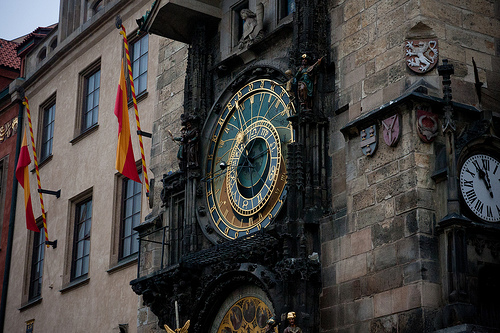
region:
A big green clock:
[162, 70, 315, 233]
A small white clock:
[442, 142, 499, 235]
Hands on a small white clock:
[475, 162, 495, 199]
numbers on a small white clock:
[459, 174, 483, 211]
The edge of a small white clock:
[449, 152, 468, 217]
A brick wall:
[331, 183, 412, 298]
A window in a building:
[28, 97, 59, 172]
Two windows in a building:
[23, 80, 107, 164]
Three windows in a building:
[16, 55, 157, 170]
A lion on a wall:
[383, 14, 447, 84]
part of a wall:
[359, 242, 389, 297]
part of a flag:
[115, 152, 142, 177]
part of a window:
[74, 247, 85, 261]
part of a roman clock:
[469, 189, 486, 218]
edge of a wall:
[407, 186, 428, 228]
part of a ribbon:
[118, 73, 144, 128]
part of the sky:
[19, 5, 44, 18]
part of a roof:
[3, 52, 13, 68]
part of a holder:
[45, 186, 60, 197]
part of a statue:
[243, 16, 259, 32]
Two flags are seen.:
[5, 35, 160, 218]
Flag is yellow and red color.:
[8, 82, 203, 235]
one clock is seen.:
[446, 130, 496, 210]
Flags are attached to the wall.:
[0, 90, 176, 240]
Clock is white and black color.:
[445, 150, 497, 216]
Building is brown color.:
[65, 158, 116, 178]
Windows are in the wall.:
[20, 87, 166, 282]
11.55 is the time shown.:
[441, 130, 497, 230]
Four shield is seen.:
[340, 20, 443, 156]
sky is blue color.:
[3, 5, 55, 27]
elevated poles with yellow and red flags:
[10, 12, 185, 248]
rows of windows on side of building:
[11, 25, 156, 310]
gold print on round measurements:
[180, 60, 302, 246]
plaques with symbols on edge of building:
[337, 85, 457, 160]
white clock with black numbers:
[436, 150, 492, 225]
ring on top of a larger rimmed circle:
[185, 65, 300, 240]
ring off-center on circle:
[185, 70, 310, 250]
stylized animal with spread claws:
[396, 11, 446, 82]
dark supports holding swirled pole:
[25, 165, 87, 255]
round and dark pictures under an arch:
[192, 243, 301, 331]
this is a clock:
[203, 82, 295, 214]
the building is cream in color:
[47, 32, 109, 330]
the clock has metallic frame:
[163, 245, 293, 260]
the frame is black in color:
[291, 92, 319, 229]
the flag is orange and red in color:
[111, 59, 131, 159]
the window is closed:
[75, 71, 103, 123]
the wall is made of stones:
[342, 170, 412, 322]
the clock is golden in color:
[221, 99, 271, 216]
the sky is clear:
[14, 4, 52, 19]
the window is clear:
[84, 76, 97, 118]